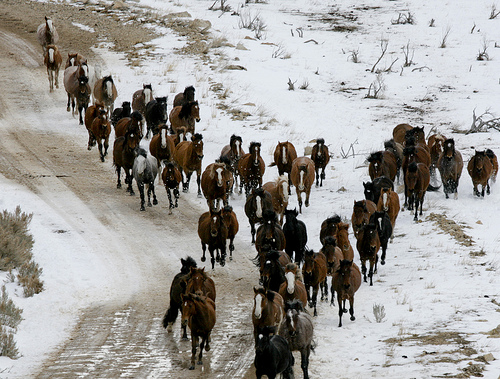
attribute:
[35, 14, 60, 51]
horse — last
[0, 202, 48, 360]
bushes — scrubby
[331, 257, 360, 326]
horse — frightened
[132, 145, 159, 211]
horse — frightened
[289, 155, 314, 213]
horse — frightened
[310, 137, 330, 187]
horse — frightened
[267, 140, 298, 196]
horse — frightened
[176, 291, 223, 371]
horse — wild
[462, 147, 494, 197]
horse — wild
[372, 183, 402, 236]
horse — wild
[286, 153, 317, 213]
horse — wild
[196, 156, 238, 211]
horse — wild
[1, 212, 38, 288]
grass — brown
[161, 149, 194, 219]
horse — grey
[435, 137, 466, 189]
horse — brown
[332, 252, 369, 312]
horse — brown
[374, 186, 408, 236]
horse — brown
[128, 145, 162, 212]
horse — ashen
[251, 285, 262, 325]
head — white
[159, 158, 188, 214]
horse — little, brown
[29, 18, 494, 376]
horses — running, fast, roaming, free, gathered, many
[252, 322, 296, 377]
horse — dark-colored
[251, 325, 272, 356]
face — white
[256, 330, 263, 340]
spot — white